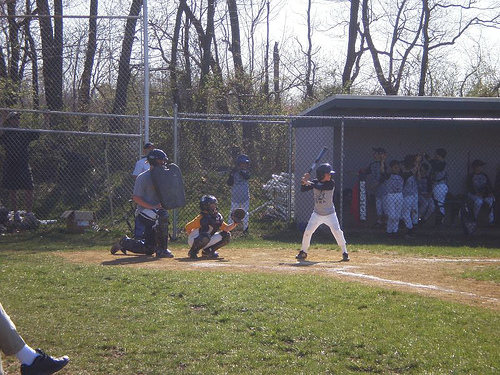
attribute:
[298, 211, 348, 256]
pants — white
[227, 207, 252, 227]
mitt — black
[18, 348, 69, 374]
shoe — black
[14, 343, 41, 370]
sock — white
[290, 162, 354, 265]
player — young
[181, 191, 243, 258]
catcher — young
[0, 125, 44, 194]
clothes — dark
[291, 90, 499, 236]
building — long, gray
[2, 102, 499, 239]
fence — high,  metal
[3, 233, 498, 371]
field — green, grassy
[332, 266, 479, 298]
line — white, long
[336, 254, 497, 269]
line — long